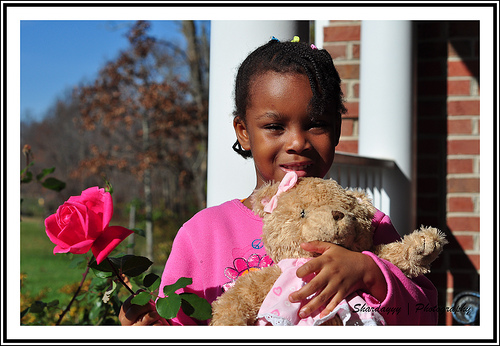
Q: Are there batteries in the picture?
A: No, there are no batteries.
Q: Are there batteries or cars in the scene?
A: No, there are no batteries or cars.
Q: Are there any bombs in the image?
A: No, there are no bombs.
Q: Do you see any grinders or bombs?
A: No, there are no bombs or grinders.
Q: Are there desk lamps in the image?
A: No, there are no desk lamps.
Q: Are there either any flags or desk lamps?
A: No, there are no desk lamps or flags.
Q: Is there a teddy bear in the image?
A: Yes, there is a teddy bear.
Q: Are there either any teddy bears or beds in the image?
A: Yes, there is a teddy bear.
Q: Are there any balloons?
A: No, there are no balloons.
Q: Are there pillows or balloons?
A: No, there are no balloons or pillows.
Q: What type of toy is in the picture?
A: The toy is a teddy bear.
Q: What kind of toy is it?
A: The toy is a teddy bear.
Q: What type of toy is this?
A: That is a teddy bear.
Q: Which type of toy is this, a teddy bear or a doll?
A: That is a teddy bear.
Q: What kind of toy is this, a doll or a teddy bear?
A: That is a teddy bear.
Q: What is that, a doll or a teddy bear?
A: That is a teddy bear.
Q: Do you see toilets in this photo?
A: No, there are no toilets.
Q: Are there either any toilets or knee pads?
A: No, there are no toilets or knee pads.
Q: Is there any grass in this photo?
A: Yes, there is grass.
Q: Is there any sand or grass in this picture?
A: Yes, there is grass.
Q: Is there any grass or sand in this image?
A: Yes, there is grass.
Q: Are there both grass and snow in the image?
A: No, there is grass but no snow.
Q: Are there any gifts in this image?
A: No, there are no gifts.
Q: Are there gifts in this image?
A: No, there are no gifts.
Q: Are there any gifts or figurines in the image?
A: No, there are no gifts or figurines.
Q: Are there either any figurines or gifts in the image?
A: No, there are no gifts or figurines.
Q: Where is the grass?
A: The grass is on the ground.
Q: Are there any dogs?
A: No, there are no dogs.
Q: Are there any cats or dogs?
A: No, there are no dogs or cats.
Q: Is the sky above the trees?
A: Yes, the sky is above the trees.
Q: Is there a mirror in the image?
A: No, there are no mirrors.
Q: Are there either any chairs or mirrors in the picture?
A: No, there are no mirrors or chairs.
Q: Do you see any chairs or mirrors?
A: No, there are no mirrors or chairs.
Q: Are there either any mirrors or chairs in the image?
A: No, there are no mirrors or chairs.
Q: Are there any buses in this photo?
A: No, there are no buses.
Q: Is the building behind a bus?
A: No, the building is behind the girl.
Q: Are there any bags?
A: No, there are no bags.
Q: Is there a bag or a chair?
A: No, there are no bags or chairs.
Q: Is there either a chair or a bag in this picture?
A: No, there are no bags or chairs.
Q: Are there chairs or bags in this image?
A: No, there are no bags or chairs.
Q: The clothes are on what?
A: The clothes are on the teddy bear.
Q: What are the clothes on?
A: The clothes are on the teddy bear.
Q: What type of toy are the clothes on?
A: The clothes are on the teddy bear.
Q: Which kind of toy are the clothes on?
A: The clothes are on the teddy bear.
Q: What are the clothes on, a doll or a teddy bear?
A: The clothes are on a teddy bear.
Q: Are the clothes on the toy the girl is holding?
A: Yes, the clothes are on the teddy bear.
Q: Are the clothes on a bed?
A: No, the clothes are on the teddy bear.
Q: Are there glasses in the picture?
A: No, there are no glasses.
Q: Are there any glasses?
A: No, there are no glasses.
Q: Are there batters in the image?
A: No, there are no batters.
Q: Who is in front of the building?
A: The girl is in front of the building.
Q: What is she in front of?
A: The girl is in front of the building.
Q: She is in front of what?
A: The girl is in front of the building.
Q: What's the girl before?
A: The girl is in front of the building.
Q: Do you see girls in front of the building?
A: Yes, there is a girl in front of the building.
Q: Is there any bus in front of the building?
A: No, there is a girl in front of the building.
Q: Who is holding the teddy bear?
A: The girl is holding the teddy bear.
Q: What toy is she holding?
A: The girl is holding the teddy bear.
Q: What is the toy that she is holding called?
A: The toy is a teddy bear.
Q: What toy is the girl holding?
A: The girl is holding the teddy bear.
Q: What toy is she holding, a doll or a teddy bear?
A: The girl is holding a teddy bear.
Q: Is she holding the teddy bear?
A: Yes, the girl is holding the teddy bear.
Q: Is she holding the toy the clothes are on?
A: Yes, the girl is holding the teddy bear.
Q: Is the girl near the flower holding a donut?
A: No, the girl is holding the teddy bear.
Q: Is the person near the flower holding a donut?
A: No, the girl is holding the teddy bear.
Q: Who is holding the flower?
A: The girl is holding the flower.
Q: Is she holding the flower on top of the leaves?
A: Yes, the girl is holding the flower.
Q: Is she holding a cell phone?
A: No, the girl is holding the flower.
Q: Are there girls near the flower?
A: Yes, there is a girl near the flower.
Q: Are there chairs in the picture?
A: No, there are no chairs.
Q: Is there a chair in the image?
A: No, there are no chairs.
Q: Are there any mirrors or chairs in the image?
A: No, there are no chairs or mirrors.